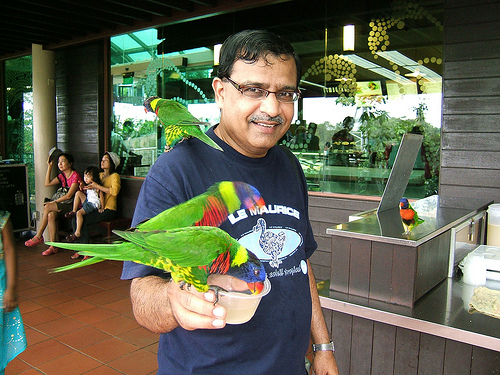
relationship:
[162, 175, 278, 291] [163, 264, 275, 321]
birds in hand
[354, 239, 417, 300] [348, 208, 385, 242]
wood on counter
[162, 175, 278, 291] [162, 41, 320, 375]
birds on man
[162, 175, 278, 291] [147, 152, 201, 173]
birds on shoulder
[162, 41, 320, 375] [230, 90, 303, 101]
man wearing glasses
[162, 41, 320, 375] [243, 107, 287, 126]
man has mustache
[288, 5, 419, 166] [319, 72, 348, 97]
window has logo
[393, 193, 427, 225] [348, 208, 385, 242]
bird on counter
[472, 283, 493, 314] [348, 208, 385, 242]
tray on counter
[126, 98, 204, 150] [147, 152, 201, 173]
bird on shoulder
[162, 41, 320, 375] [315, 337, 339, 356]
man wearing watch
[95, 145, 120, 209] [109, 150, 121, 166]
woman wearing hat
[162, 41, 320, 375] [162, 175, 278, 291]
man holding birds